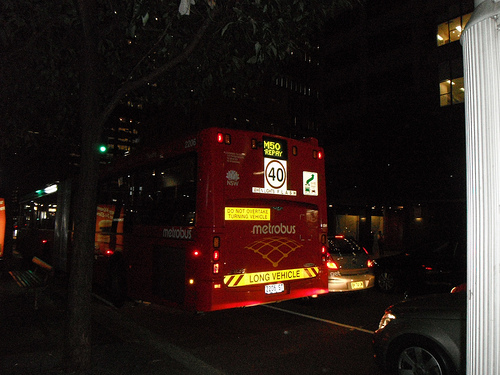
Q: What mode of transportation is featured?
A: Bus.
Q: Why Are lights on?
A: It is during the night.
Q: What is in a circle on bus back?
A: Number.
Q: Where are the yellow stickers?
A: On bus.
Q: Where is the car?
A: Behind bus.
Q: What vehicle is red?
A: Fire truck.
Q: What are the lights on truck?
A: Brake lights.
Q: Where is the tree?
A: Near street.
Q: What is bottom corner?
A: Front end of car.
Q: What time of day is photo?
A: Dark and nighttime.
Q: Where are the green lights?
A: On street.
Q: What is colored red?
A: The bus.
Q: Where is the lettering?
A: Bus.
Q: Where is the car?
A: Behind bus.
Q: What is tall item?
A: Tree.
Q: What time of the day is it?
A: Night time.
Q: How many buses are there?
A: One.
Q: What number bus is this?
A: M50.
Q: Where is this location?
A: Street.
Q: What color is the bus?
A: Red.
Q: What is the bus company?
A: Metrobus.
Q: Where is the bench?
A: Sidewalk.